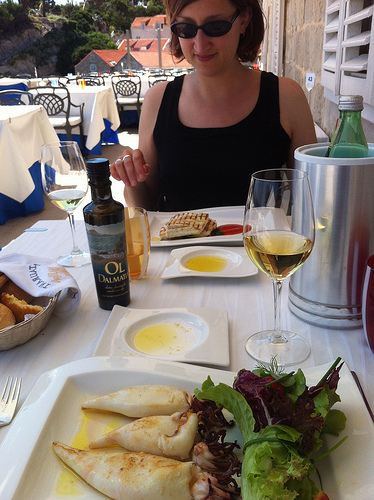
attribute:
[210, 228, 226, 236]
broccoli — green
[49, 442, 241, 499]
lobster — fried, creal color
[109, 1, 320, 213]
lady — light skinned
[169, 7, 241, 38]
goggles — worn, black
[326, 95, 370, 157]
bottle — wine, green, glass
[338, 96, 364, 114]
top — closed, metal, silver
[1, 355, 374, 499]
plate — white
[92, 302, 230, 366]
bowl — white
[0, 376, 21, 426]
fork — silver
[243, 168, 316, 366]
glass — clear, part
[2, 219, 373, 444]
table — white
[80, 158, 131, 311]
bottle — oil, glass, dark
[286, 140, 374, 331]
bucket — silver, metal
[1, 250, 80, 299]
napkin — white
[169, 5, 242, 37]
sunglasses — black, plastic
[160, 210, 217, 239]
fish — grilled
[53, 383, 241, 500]
squid — baked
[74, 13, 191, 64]
roof — red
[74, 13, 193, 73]
house — brick